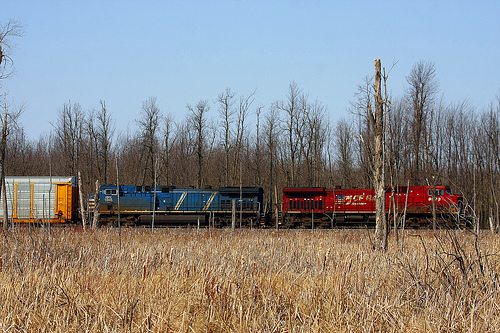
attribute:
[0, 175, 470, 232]
train — here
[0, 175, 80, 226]
car — silver, yellow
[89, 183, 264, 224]
car — blue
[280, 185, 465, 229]
car — red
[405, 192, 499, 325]
bush — brown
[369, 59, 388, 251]
trunk — narrow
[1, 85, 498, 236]
trees — brown, bare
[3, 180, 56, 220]
doors — silver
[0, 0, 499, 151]
sky — blue, clear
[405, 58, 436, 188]
tree — bare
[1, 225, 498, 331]
grass — dead, brown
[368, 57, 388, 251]
tree — tall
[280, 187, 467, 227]
engine — red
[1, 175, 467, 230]
locomotives — red, blue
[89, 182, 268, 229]
locomotive — blue